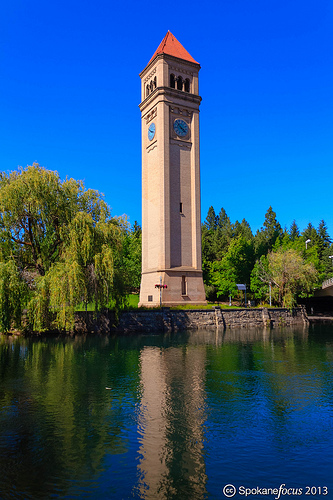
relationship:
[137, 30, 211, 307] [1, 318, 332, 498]
tower near water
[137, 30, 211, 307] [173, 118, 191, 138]
tower has clock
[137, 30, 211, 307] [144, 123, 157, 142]
tower has clock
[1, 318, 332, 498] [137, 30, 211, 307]
water near tower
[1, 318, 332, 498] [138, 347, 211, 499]
water has reflection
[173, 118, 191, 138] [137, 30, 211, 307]
clock on tower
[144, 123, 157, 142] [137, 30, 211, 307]
clock on tower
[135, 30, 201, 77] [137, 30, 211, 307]
roof of tower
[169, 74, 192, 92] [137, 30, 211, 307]
windows in tower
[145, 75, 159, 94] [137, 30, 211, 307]
windows in tower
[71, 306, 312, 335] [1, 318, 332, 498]
wall at water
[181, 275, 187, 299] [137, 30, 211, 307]
door in tower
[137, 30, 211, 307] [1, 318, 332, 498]
tower by water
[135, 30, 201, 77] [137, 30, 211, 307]
roof on tower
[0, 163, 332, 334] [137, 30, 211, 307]
trees behind tower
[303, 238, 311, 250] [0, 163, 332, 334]
pole in trees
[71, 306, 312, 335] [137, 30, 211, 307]
wall by tower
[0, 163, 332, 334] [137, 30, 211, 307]
trees near tower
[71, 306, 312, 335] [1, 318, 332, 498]
wall near water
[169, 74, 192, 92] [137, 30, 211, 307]
windows on tower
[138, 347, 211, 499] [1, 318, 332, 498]
reflection in water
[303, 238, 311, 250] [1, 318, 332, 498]
pole near water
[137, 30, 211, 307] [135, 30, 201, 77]
tower with roof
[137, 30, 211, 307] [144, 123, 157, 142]
tower with clock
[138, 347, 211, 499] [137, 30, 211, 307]
reflection of tower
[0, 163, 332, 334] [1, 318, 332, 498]
trees near water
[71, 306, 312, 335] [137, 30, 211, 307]
wall near tower